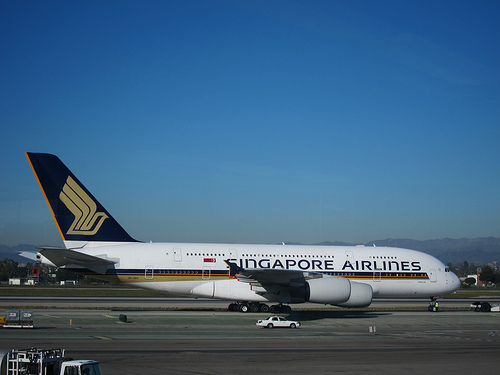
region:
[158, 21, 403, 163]
this is the sky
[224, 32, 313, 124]
the sky is blue in color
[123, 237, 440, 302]
this is a jet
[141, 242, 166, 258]
the jet is white in color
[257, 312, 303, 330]
this is a car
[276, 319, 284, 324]
the car is white in color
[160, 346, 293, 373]
this is a ran way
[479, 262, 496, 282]
this is a tree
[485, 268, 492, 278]
the tree has green leaves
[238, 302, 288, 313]
these are the wheels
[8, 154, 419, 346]
Plane at the airport.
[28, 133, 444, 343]
Plane on the runway.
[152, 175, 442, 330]
Words on the plane.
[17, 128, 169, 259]
Design on the wings.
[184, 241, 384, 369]
Engines on the plane.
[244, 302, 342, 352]
Car by the plane.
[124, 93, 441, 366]
Sky behind the plane.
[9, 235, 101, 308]
Mountains behind the plane.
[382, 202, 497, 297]
Trees in the background.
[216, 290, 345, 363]
White car on the road.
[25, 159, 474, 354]
plane says singapore airlines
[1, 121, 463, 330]
plane white blue gold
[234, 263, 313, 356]
one white vehicle next to plane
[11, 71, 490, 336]
no clouds in sky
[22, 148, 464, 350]
plane on tarmac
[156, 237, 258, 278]
red sign on plane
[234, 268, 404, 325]
two plane engines visible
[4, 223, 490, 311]
mountains behind plane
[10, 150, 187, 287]
plane tail blue gold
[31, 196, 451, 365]
plane parked on tar mac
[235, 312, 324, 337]
small white car on tarmac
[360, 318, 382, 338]
small white object on the tarmac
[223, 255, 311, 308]
black tip of wings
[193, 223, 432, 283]
black words on the air plane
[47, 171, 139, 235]
gold logo on plane's tail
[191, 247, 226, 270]
red symbol on plane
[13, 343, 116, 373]
white truck in the foreground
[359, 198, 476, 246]
tall mountain range in the distance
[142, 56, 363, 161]
clear blue skies overhead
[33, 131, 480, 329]
large passenger plane on the tarmac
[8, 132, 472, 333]
airplane on the ground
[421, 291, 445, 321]
front wheels of an airplane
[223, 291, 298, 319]
rear wheels on a plane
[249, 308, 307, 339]
vehicle on an airport runway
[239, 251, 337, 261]
windows on an airplane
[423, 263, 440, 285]
door on an airplane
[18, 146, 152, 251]
tail wing on an airplane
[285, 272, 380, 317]
engines on an airplane wing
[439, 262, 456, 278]
cockpit windows on an airplane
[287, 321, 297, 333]
front wheel on a vehicle